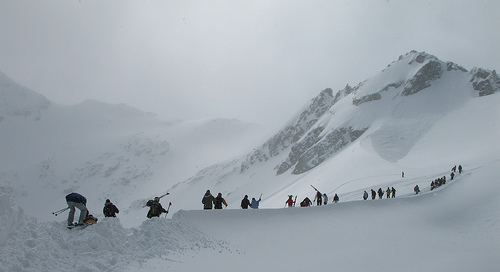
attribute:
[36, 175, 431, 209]
skiers — moving, bending, walking, lined, travelling, hiking, cold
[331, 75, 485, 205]
mountain — white, gray, grey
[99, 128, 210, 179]
snow — white, untouched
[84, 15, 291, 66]
sky — gray, hazy, foggy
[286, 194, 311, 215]
coat — red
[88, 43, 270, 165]
clouds — gray